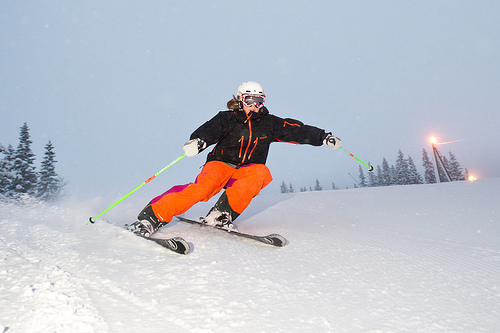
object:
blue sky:
[0, 0, 499, 210]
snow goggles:
[236, 94, 267, 109]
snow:
[1, 171, 500, 333]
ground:
[1, 173, 499, 331]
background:
[0, 0, 495, 221]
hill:
[0, 177, 500, 333]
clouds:
[0, 0, 500, 182]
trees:
[34, 140, 68, 205]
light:
[429, 135, 438, 145]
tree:
[421, 149, 437, 184]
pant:
[136, 161, 273, 229]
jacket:
[184, 110, 333, 169]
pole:
[83, 148, 193, 226]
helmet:
[235, 80, 266, 98]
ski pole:
[336, 141, 375, 173]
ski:
[110, 223, 191, 257]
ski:
[167, 215, 287, 249]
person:
[124, 79, 344, 237]